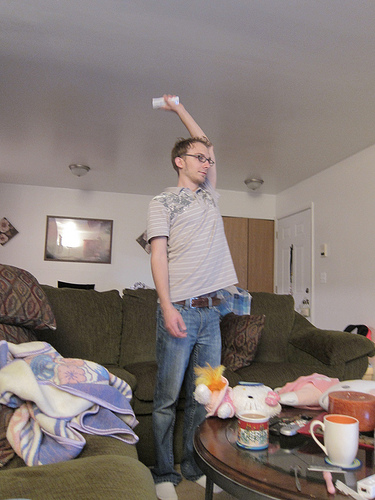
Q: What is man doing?
A: Standing.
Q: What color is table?
A: Brown.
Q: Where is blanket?
A: On couch.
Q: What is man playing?
A: Wii.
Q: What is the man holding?
A: A Wii controller.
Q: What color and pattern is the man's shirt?
A: Gray striped.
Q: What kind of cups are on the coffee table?
A: Coffee cups.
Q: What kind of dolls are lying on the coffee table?
A: Hello Kitty.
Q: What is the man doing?
A: Standing and holding a game controller.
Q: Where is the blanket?
A: Laying on the couch.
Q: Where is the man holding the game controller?
A: Over his head.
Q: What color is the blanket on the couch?
A: White, purple, and pink.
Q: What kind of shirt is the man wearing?
A: Polo shirt.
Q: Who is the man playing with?
A: Himself.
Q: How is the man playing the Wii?
A: Standing up.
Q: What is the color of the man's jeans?
A: Blue.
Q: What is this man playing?
A: Nintendo Wii.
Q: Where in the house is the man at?
A: Living room.